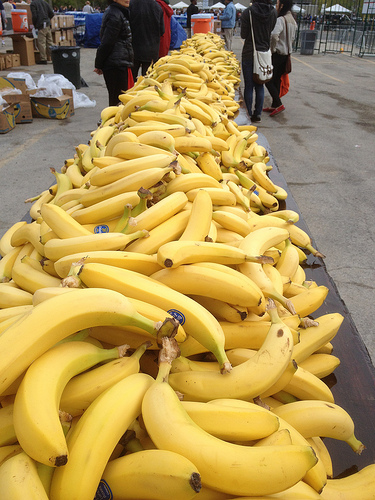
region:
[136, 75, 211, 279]
Bananas on the table.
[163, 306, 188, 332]
Some of the bananas have blue stickers.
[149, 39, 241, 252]
A long table full of bananas.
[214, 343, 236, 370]
Green stem of the banana.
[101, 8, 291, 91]
People standing by the table.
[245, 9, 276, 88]
A person with a white shoulder bag.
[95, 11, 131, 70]
The person has a black coat.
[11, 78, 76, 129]
Boxes on the ground.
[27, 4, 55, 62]
Person standing by the cardboard boxes.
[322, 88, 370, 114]
The ground is wet.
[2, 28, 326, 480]
Large pile of bananas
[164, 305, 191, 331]
Blue stickers on the bananas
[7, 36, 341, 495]
The bananas are yellow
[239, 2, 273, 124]
Person carrying a white bag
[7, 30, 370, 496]
Bananas on a dark wooden table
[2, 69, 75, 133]
Brown boxes on the ground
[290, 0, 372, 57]
The fence is black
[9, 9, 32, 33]
Large orange cooler with white lid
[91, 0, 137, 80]
Person wearing a black jacket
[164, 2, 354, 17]
White tents behind the bananas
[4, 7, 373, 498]
picture taken outside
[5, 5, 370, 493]
picture taken outdoors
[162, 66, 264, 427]
a table full of bananas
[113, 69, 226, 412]
the bananas are yellow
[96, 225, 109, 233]
a sticker on the banana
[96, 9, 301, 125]
people are standing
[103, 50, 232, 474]
hundreds of bananas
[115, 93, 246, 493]
the bananas are not in bunches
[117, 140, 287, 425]
the bananas are in single servings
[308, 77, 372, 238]
the ground is gray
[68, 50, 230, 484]
these are the banana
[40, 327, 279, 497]
the banana are ripe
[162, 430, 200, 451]
the banana is yellow in color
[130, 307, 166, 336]
this is the stalk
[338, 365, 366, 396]
this is a table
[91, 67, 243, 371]
the banana are in a row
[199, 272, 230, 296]
the banana is attractive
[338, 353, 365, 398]
the table is wooden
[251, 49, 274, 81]
this is a bag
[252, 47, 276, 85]
the bag is brown in color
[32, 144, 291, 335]
lots of bananas on a table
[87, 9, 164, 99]
a person wearing a jacket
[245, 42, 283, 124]
a person wearing jeans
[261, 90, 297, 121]
a person wearing shoes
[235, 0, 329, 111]
two people standing near bananas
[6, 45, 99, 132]
boxes in the background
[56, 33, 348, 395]
a bunch of bananas on a table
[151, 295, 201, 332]
a little blue sticker on a banana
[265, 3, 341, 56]
a woman wearing a grey shirt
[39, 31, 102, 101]
a black garbage can